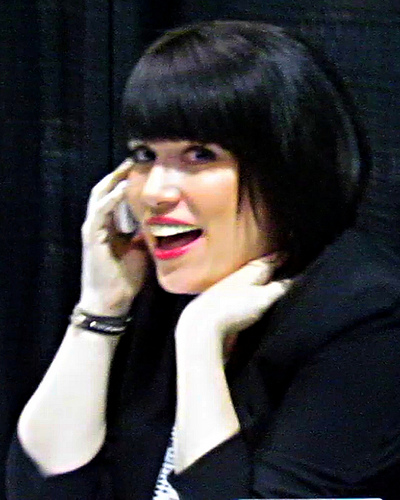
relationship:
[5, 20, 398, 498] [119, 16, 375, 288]
woman has hair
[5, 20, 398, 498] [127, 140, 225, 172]
woman has eyes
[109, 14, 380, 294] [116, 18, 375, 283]
hairstyle has hairstyle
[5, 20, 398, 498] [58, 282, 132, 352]
woman has wrist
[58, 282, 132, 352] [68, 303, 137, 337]
wrist has bracelet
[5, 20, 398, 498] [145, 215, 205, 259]
woman has smile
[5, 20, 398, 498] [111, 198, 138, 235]
woman talking on phone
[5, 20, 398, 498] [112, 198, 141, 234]
woman holding cell phone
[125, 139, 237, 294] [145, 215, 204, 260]
face has mouth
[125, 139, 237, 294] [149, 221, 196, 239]
face has teeth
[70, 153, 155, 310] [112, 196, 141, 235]
hand holding cellphone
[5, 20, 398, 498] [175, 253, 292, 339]
woman has hand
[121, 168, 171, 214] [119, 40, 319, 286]
cheek has face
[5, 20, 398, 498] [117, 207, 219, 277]
woman has mouth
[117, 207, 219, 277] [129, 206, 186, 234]
mouth has lipstick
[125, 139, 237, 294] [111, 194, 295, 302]
face with makeup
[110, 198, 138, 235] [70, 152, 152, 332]
cellphone in hand